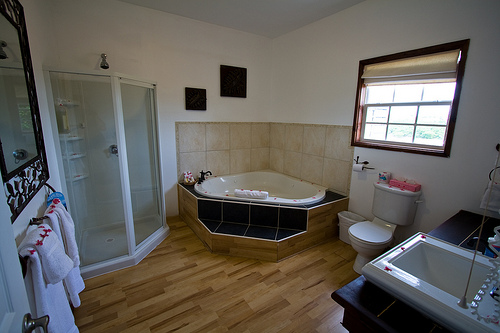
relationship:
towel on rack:
[15, 224, 75, 285] [4, 177, 96, 329]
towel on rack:
[44, 188, 86, 267] [4, 177, 96, 329]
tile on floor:
[195, 198, 310, 240] [152, 249, 342, 330]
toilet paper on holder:
[353, 162, 367, 171] [354, 155, 374, 171]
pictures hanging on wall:
[181, 82, 208, 112] [37, 0, 269, 224]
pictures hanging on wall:
[218, 60, 249, 97] [37, 0, 269, 224]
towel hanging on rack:
[15, 224, 75, 285] [18, 172, 63, 276]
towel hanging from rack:
[15, 224, 75, 285] [21, 181, 60, 276]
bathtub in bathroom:
[176, 168, 346, 264] [0, 0, 499, 332]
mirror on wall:
[1, 2, 51, 222] [4, 0, 137, 320]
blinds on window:
[362, 50, 462, 82] [358, 48, 461, 147]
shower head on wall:
[98, 52, 112, 69] [74, 78, 129, 240]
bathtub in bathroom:
[172, 116, 357, 263] [37, 0, 499, 330]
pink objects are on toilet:
[368, 172, 430, 207] [342, 184, 428, 270]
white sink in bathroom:
[372, 228, 497, 323] [52, 35, 476, 315]